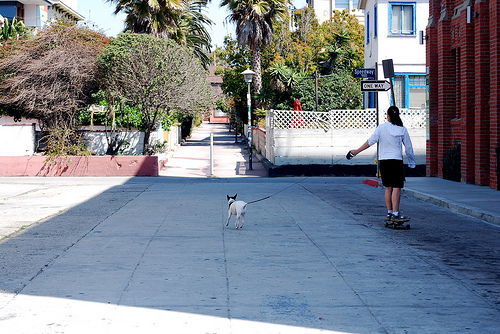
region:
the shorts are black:
[381, 159, 409, 190]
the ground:
[270, 238, 344, 288]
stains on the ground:
[428, 229, 480, 271]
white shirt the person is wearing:
[378, 126, 405, 158]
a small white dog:
[224, 192, 248, 231]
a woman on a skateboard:
[347, 103, 417, 228]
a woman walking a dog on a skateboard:
[223, 105, 413, 228]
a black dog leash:
[246, 150, 353, 205]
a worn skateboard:
[382, 214, 409, 231]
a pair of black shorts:
[375, 158, 404, 186]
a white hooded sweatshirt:
[368, 120, 415, 164]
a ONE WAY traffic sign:
[361, 79, 393, 91]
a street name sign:
[351, 65, 376, 78]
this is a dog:
[215, 185, 256, 230]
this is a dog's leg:
[233, 210, 238, 228]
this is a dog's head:
[223, 190, 242, 209]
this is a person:
[335, 102, 424, 237]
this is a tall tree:
[99, 20, 216, 160]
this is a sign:
[357, 75, 390, 95]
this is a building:
[359, 4, 436, 182]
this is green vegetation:
[271, 21, 370, 174]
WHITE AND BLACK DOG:
[221, 188, 248, 233]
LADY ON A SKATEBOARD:
[374, 99, 416, 245]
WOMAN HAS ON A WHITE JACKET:
[387, 139, 401, 155]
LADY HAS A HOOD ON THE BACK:
[388, 126, 401, 138]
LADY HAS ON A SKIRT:
[386, 166, 403, 185]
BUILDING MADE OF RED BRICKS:
[474, 45, 489, 73]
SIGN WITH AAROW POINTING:
[358, 80, 395, 91]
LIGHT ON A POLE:
[241, 70, 256, 87]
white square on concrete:
[368, 304, 498, 332]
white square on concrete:
[228, 305, 390, 332]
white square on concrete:
[108, 304, 233, 332]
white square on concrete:
[0, 287, 125, 329]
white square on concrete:
[340, 268, 485, 305]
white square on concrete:
[223, 258, 366, 308]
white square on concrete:
[118, 259, 230, 304]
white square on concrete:
[25, 259, 137, 300]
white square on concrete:
[48, 233, 151, 262]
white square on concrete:
[137, 235, 226, 259]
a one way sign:
[362, 80, 388, 91]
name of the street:
[357, 66, 374, 76]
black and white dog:
[225, 191, 247, 224]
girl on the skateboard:
[354, 99, 416, 230]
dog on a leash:
[192, 105, 362, 236]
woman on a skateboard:
[311, 92, 439, 235]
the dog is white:
[218, 184, 258, 235]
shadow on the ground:
[3, 172, 498, 332]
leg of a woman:
[390, 185, 397, 212]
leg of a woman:
[384, 186, 390, 213]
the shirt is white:
[368, 122, 415, 164]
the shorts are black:
[374, 156, 406, 190]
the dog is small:
[227, 191, 251, 228]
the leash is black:
[243, 153, 352, 204]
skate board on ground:
[383, 211, 412, 227]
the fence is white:
[263, 109, 427, 128]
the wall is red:
[0, 154, 157, 174]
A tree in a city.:
[226, 2, 263, 109]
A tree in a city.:
[101, 30, 187, 152]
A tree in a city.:
[273, 59, 292, 102]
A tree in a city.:
[293, 68, 360, 112]